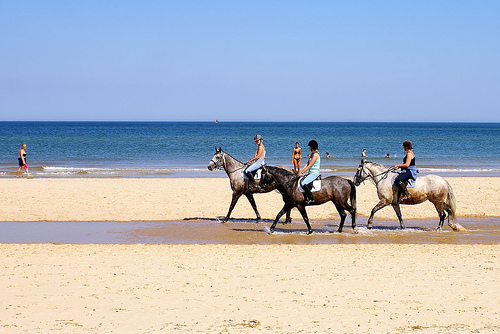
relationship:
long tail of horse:
[445, 185, 457, 237] [362, 182, 459, 238]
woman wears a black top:
[373, 115, 445, 246] [407, 151, 410, 164]